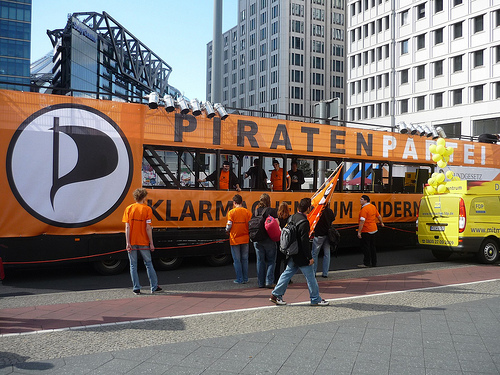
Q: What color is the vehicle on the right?
A: Yellow.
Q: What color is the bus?
A: Orange.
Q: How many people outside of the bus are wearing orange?
A: Three.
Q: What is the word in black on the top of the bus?
A: Piraten.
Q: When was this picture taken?
A: Daytime.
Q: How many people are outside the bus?
A: Seven.